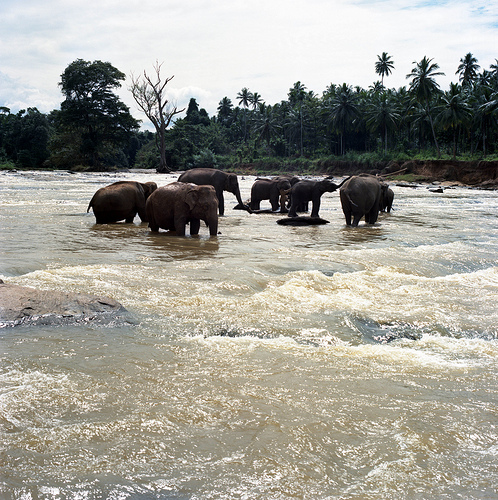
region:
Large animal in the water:
[143, 176, 226, 257]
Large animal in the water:
[79, 160, 138, 232]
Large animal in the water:
[184, 158, 246, 209]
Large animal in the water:
[249, 171, 287, 212]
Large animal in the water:
[337, 169, 391, 233]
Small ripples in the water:
[30, 450, 79, 498]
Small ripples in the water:
[77, 456, 122, 495]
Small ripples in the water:
[126, 452, 180, 498]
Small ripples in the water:
[184, 455, 215, 495]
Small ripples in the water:
[252, 437, 289, 486]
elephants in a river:
[81, 164, 395, 245]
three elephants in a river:
[83, 165, 250, 238]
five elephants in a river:
[79, 163, 337, 236]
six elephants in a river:
[83, 163, 393, 239]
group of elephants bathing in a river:
[81, 161, 395, 243]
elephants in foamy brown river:
[1, 165, 496, 497]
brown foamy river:
[2, 239, 494, 497]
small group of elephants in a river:
[82, 163, 397, 239]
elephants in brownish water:
[80, 159, 395, 233]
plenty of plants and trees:
[0, 52, 496, 171]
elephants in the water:
[80, 147, 409, 257]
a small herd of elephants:
[84, 157, 404, 243]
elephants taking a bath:
[71, 161, 403, 241]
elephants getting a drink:
[79, 161, 401, 243]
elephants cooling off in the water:
[67, 161, 402, 241]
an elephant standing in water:
[145, 180, 222, 241]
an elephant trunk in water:
[208, 195, 220, 252]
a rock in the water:
[1, 276, 126, 340]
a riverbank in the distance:
[209, 145, 487, 191]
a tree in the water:
[146, 117, 178, 183]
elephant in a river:
[151, 182, 220, 243]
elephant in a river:
[79, 167, 144, 226]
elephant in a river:
[190, 165, 246, 208]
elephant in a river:
[253, 173, 286, 212]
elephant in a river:
[289, 184, 328, 223]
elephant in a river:
[342, 177, 393, 236]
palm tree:
[400, 69, 449, 155]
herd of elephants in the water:
[121, 159, 431, 251]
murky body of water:
[182, 355, 302, 411]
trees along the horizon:
[210, 79, 475, 148]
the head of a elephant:
[179, 173, 245, 233]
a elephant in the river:
[138, 175, 244, 249]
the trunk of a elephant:
[195, 213, 236, 272]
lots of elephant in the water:
[74, 139, 391, 269]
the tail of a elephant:
[331, 181, 374, 215]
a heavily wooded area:
[60, 50, 432, 203]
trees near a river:
[57, 36, 444, 245]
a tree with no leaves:
[123, 38, 231, 141]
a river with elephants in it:
[80, 106, 399, 257]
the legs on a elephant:
[155, 211, 204, 247]